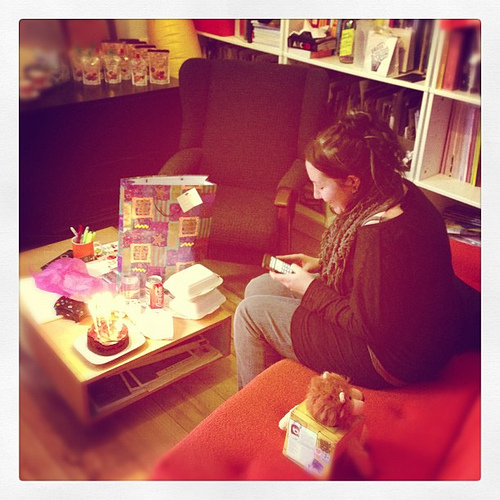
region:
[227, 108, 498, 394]
young lady sitting on couch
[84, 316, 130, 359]
small brown cake on plate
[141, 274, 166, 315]
one red and white coca cola can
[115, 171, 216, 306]
large multicolored gift bag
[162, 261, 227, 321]
two white styrofoam containers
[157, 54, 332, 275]
large brown chair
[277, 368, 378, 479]
stuffed lion in square box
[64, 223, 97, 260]
group of writing utensils in mug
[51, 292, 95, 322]
black video game controller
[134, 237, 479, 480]
large red sofa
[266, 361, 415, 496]
Lion on a couch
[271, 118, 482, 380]
Woman on a couch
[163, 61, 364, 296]
Chair in a room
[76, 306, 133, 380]
Cake on a table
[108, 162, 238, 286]
Bag on a table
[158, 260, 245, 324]
Two food containers on a table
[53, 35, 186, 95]
Food on a stand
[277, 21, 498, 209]
Book shelf in a room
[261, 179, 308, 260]
Wood arm on a chair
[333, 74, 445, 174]
Books on a shelf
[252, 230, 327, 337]
the girl is texting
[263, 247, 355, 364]
the girl is texting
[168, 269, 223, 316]
Two white boxes on top of one another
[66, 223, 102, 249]
Crayons in a red cup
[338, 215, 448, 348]
Women is wearing a black shirt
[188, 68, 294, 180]
A chair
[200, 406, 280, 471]
The red couch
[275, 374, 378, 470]
A toy is on the red couch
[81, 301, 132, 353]
Small birthday cake on a white plate.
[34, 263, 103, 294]
Pink tissue paper on table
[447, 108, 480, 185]
books on the bookshelf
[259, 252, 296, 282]
Smartphone in womens hands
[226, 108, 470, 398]
Woman sitting on chair holding cell phone.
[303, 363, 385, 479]
Brown stuffed lion sitting on chair.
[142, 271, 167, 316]
Coca Cola can sitting on coffee table.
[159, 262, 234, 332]
Two styrofoam containers sitting on table.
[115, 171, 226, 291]
Gift bag sitting on coffee table.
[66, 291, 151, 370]
Chocolate cake with candles sitting on coffee table.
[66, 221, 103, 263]
Orange cup holding pens sitting on coffee table.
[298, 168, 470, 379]
Woman dressed in black top.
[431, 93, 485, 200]
Books stacked on shelf.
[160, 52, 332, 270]
Brown chair sitting in corner next to book shelf.